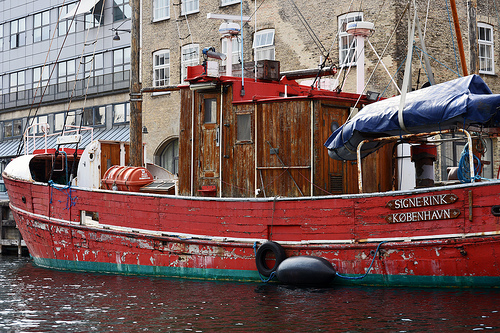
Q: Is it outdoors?
A: Yes, it is outdoors.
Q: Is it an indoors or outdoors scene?
A: It is outdoors.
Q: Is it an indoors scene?
A: No, it is outdoors.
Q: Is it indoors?
A: No, it is outdoors.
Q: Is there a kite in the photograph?
A: No, there are no kites.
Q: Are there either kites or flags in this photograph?
A: No, there are no kites or flags.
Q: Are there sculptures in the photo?
A: No, there are no sculptures.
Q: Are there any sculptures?
A: No, there are no sculptures.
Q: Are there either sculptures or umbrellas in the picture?
A: No, there are no sculptures or umbrellas.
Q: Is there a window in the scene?
A: Yes, there is a window.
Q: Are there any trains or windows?
A: Yes, there is a window.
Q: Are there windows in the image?
A: Yes, there is a window.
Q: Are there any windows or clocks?
A: Yes, there is a window.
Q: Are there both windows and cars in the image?
A: No, there is a window but no cars.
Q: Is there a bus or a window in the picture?
A: Yes, there is a window.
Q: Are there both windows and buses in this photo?
A: No, there is a window but no buses.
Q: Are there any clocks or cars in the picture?
A: No, there are no cars or clocks.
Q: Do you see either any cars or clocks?
A: No, there are no cars or clocks.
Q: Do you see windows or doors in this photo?
A: Yes, there is a window.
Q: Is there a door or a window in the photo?
A: Yes, there is a window.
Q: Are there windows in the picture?
A: Yes, there is a window.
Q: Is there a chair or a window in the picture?
A: Yes, there is a window.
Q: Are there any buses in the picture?
A: No, there are no buses.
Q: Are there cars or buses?
A: No, there are no buses or cars.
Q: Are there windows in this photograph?
A: Yes, there is a window.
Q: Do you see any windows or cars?
A: Yes, there is a window.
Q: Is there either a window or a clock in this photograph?
A: Yes, there is a window.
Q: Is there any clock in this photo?
A: No, there are no clocks.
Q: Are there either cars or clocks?
A: No, there are no clocks or cars.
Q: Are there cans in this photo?
A: No, there are no cans.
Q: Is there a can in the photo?
A: No, there are no cans.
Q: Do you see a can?
A: No, there are no cans.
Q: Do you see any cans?
A: No, there are no cans.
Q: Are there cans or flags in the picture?
A: No, there are no cans or flags.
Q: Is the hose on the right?
A: Yes, the hose is on the right of the image.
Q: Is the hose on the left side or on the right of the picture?
A: The hose is on the right of the image.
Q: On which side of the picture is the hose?
A: The hose is on the right of the image.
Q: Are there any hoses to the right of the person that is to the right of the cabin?
A: Yes, there is a hose to the right of the person.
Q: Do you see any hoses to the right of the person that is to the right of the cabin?
A: Yes, there is a hose to the right of the person.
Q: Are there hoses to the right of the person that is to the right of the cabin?
A: Yes, there is a hose to the right of the person.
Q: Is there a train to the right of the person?
A: No, there is a hose to the right of the person.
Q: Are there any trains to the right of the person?
A: No, there is a hose to the right of the person.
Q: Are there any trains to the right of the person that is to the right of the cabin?
A: No, there is a hose to the right of the person.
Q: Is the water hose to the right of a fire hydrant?
A: No, the water hose is to the right of the person.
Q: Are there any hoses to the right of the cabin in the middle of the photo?
A: Yes, there is a hose to the right of the cabin.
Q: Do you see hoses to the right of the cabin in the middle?
A: Yes, there is a hose to the right of the cabin.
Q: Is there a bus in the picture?
A: No, there are no buses.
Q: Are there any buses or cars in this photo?
A: No, there are no buses or cars.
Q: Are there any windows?
A: Yes, there is a window.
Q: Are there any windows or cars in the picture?
A: Yes, there is a window.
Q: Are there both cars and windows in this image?
A: No, there is a window but no cars.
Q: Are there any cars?
A: No, there are no cars.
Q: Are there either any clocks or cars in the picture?
A: No, there are no cars or clocks.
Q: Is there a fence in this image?
A: Yes, there is a fence.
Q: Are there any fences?
A: Yes, there is a fence.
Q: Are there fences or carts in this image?
A: Yes, there is a fence.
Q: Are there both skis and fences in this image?
A: No, there is a fence but no skis.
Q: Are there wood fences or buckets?
A: Yes, there is a wood fence.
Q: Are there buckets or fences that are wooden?
A: Yes, the fence is wooden.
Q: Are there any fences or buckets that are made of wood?
A: Yes, the fence is made of wood.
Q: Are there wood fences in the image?
A: Yes, there is a wood fence.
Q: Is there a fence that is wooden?
A: Yes, there is a fence that is wooden.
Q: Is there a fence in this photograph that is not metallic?
A: Yes, there is a wooden fence.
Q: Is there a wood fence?
A: Yes, there is a fence that is made of wood.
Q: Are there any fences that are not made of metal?
A: Yes, there is a fence that is made of wood.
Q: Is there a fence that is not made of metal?
A: Yes, there is a fence that is made of wood.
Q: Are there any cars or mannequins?
A: No, there are no cars or mannequins.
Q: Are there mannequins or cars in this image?
A: No, there are no cars or mannequins.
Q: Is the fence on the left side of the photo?
A: Yes, the fence is on the left of the image.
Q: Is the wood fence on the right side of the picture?
A: No, the fence is on the left of the image.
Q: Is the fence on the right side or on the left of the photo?
A: The fence is on the left of the image.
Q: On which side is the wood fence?
A: The fence is on the left of the image.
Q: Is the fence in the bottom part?
A: Yes, the fence is in the bottom of the image.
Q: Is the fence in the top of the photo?
A: No, the fence is in the bottom of the image.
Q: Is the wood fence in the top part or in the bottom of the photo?
A: The fence is in the bottom of the image.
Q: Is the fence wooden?
A: Yes, the fence is wooden.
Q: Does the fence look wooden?
A: Yes, the fence is wooden.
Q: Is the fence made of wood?
A: Yes, the fence is made of wood.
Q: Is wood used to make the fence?
A: Yes, the fence is made of wood.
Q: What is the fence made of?
A: The fence is made of wood.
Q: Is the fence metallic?
A: No, the fence is wooden.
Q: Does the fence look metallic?
A: No, the fence is wooden.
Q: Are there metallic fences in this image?
A: No, there is a fence but it is wooden.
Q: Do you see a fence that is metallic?
A: No, there is a fence but it is wooden.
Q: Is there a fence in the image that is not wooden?
A: No, there is a fence but it is wooden.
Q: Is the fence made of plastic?
A: No, the fence is made of wood.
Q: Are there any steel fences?
A: No, there is a fence but it is made of wood.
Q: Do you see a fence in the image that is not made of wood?
A: No, there is a fence but it is made of wood.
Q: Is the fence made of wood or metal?
A: The fence is made of wood.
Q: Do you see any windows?
A: Yes, there is a window.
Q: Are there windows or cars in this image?
A: Yes, there is a window.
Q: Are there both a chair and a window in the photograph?
A: No, there is a window but no chairs.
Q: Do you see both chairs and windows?
A: No, there is a window but no chairs.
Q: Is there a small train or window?
A: Yes, there is a small window.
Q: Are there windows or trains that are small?
A: Yes, the window is small.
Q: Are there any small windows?
A: Yes, there is a small window.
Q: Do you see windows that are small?
A: Yes, there is a window that is small.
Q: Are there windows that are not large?
A: Yes, there is a small window.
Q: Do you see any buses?
A: No, there are no buses.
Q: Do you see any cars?
A: No, there are no cars.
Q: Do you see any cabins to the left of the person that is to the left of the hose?
A: Yes, there is a cabin to the left of the person.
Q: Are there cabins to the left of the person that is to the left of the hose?
A: Yes, there is a cabin to the left of the person.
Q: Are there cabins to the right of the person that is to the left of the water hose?
A: No, the cabin is to the left of the person.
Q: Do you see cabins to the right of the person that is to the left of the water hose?
A: No, the cabin is to the left of the person.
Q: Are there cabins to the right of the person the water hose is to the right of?
A: No, the cabin is to the left of the person.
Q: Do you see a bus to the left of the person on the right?
A: No, there is a cabin to the left of the person.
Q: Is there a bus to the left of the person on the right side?
A: No, there is a cabin to the left of the person.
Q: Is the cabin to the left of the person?
A: Yes, the cabin is to the left of the person.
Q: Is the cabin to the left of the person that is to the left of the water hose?
A: Yes, the cabin is to the left of the person.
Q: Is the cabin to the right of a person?
A: No, the cabin is to the left of a person.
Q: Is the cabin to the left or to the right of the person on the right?
A: The cabin is to the left of the person.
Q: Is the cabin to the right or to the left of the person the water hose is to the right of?
A: The cabin is to the left of the person.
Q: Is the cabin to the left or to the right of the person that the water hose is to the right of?
A: The cabin is to the left of the person.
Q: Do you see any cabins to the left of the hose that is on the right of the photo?
A: Yes, there is a cabin to the left of the water hose.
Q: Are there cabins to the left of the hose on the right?
A: Yes, there is a cabin to the left of the water hose.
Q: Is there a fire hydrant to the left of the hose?
A: No, there is a cabin to the left of the hose.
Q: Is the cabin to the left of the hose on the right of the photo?
A: Yes, the cabin is to the left of the hose.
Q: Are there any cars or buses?
A: No, there are no cars or buses.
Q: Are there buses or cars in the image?
A: No, there are no cars or buses.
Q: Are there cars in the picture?
A: No, there are no cars.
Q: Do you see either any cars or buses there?
A: No, there are no cars or buses.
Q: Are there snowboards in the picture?
A: No, there are no snowboards.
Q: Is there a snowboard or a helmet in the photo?
A: No, there are no snowboards or helmets.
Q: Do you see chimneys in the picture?
A: No, there are no chimneys.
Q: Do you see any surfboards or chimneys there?
A: No, there are no chimneys or surfboards.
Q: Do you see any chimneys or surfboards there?
A: No, there are no chimneys or surfboards.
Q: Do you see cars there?
A: No, there are no cars.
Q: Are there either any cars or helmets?
A: No, there are no cars or helmets.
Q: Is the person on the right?
A: Yes, the person is on the right of the image.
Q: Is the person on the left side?
A: No, the person is on the right of the image.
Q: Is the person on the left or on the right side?
A: The person is on the right of the image.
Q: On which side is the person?
A: The person is on the right of the image.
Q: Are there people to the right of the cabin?
A: Yes, there is a person to the right of the cabin.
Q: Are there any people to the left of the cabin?
A: No, the person is to the right of the cabin.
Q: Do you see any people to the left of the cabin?
A: No, the person is to the right of the cabin.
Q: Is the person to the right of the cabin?
A: Yes, the person is to the right of the cabin.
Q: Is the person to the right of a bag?
A: No, the person is to the right of the cabin.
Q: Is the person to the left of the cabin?
A: No, the person is to the right of the cabin.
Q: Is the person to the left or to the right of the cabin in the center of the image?
A: The person is to the right of the cabin.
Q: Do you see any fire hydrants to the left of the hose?
A: No, there is a person to the left of the hose.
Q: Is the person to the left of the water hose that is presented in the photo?
A: Yes, the person is to the left of the water hose.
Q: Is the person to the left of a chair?
A: No, the person is to the left of the water hose.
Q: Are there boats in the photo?
A: Yes, there is a boat.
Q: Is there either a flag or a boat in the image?
A: Yes, there is a boat.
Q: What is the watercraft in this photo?
A: The watercraft is a boat.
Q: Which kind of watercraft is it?
A: The watercraft is a boat.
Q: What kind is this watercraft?
A: This is a boat.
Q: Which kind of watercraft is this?
A: This is a boat.